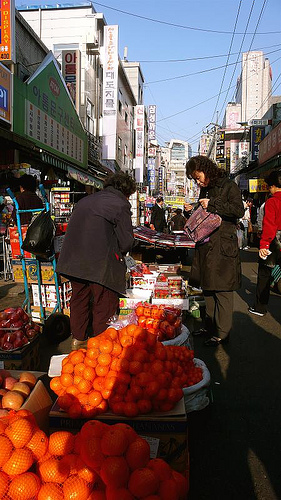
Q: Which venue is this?
A: This is a market.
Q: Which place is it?
A: It is a market.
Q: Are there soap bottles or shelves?
A: No, there are no shelves or soap bottles.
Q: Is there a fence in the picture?
A: No, there are no fences.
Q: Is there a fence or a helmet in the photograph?
A: No, there are no fences or helmets.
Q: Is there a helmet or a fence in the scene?
A: No, there are no fences or helmets.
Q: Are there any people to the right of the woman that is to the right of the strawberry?
A: Yes, there is a person to the right of the woman.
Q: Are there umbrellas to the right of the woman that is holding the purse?
A: No, there is a person to the right of the woman.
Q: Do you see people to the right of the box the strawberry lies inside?
A: Yes, there is a person to the right of the box.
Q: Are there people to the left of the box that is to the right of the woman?
A: No, the person is to the right of the box.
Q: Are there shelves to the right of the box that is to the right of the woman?
A: No, there is a person to the right of the box.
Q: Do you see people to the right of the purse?
A: Yes, there is a person to the right of the purse.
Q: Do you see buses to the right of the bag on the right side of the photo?
A: No, there is a person to the right of the purse.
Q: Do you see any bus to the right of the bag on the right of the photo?
A: No, there is a person to the right of the purse.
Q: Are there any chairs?
A: No, there are no chairs.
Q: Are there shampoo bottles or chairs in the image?
A: No, there are no chairs or shampoo bottles.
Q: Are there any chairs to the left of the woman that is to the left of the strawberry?
A: No, there is a box to the left of the woman.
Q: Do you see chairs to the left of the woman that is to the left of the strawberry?
A: No, there is a box to the left of the woman.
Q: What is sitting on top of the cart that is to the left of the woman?
A: The box is sitting on top of the cart.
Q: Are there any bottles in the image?
A: No, there are no bottles.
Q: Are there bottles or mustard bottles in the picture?
A: No, there are no bottles or mustard bottles.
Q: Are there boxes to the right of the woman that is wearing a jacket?
A: Yes, there is a box to the right of the woman.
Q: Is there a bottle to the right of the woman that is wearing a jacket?
A: No, there is a box to the right of the woman.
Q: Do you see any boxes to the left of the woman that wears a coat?
A: Yes, there is a box to the left of the woman.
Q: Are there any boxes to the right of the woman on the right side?
A: No, the box is to the left of the woman.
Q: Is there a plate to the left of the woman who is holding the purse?
A: No, there is a box to the left of the woman.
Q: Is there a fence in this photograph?
A: No, there are no fences.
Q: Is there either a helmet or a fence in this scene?
A: No, there are no fences or helmets.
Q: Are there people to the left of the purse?
A: Yes, there is a person to the left of the purse.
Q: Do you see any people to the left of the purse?
A: Yes, there is a person to the left of the purse.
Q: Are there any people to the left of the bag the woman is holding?
A: Yes, there is a person to the left of the purse.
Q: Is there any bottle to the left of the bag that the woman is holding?
A: No, there is a person to the left of the purse.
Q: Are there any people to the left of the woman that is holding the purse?
A: Yes, there is a person to the left of the woman.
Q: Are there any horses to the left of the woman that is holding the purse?
A: No, there is a person to the left of the woman.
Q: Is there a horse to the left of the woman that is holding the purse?
A: No, there is a person to the left of the woman.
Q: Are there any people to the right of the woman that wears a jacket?
A: Yes, there is a person to the right of the woman.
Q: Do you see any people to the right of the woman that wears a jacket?
A: Yes, there is a person to the right of the woman.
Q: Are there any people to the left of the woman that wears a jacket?
A: No, the person is to the right of the woman.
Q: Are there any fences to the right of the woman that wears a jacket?
A: No, there is a person to the right of the woman.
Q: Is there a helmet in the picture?
A: No, there are no helmets.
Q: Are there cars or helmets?
A: No, there are no helmets or cars.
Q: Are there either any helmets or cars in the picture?
A: No, there are no helmets or cars.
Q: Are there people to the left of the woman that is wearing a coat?
A: Yes, there is a person to the left of the woman.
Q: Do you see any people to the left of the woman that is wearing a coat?
A: Yes, there is a person to the left of the woman.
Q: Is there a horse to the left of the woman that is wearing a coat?
A: No, there is a person to the left of the woman.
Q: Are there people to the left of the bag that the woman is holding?
A: Yes, there is a person to the left of the purse.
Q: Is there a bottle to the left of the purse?
A: No, there is a person to the left of the purse.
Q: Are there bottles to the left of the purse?
A: No, there is a person to the left of the purse.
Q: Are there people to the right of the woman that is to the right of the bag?
A: Yes, there is a person to the right of the woman.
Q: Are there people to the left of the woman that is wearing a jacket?
A: No, the person is to the right of the woman.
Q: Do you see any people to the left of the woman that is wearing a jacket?
A: No, the person is to the right of the woman.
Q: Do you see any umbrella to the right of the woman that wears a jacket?
A: No, there is a person to the right of the woman.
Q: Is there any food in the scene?
A: Yes, there is food.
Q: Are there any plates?
A: No, there are no plates.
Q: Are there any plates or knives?
A: No, there are no plates or knives.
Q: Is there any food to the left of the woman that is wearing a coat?
A: Yes, there is food to the left of the woman.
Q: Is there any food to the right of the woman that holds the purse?
A: No, the food is to the left of the woman.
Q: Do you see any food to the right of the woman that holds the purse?
A: No, the food is to the left of the woman.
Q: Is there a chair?
A: No, there are no chairs.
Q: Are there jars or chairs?
A: No, there are no chairs or jars.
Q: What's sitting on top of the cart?
A: The box is sitting on top of the cart.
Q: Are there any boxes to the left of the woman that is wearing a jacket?
A: Yes, there is a box to the left of the woman.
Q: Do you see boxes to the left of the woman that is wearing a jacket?
A: Yes, there is a box to the left of the woman.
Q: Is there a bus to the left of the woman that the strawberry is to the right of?
A: No, there is a box to the left of the woman.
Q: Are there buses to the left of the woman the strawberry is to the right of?
A: No, there is a box to the left of the woman.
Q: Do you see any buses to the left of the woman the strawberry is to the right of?
A: No, there is a box to the left of the woman.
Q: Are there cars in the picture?
A: No, there are no cars.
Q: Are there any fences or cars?
A: No, there are no cars or fences.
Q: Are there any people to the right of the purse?
A: Yes, there is a person to the right of the purse.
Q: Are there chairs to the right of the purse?
A: No, there is a person to the right of the purse.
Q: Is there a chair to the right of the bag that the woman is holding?
A: No, there is a person to the right of the purse.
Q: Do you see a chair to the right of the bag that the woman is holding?
A: No, there is a person to the right of the purse.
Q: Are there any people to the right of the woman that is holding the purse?
A: Yes, there is a person to the right of the woman.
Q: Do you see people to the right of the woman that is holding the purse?
A: Yes, there is a person to the right of the woman.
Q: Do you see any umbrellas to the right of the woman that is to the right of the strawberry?
A: No, there is a person to the right of the woman.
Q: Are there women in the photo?
A: Yes, there is a woman.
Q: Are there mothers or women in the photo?
A: Yes, there is a woman.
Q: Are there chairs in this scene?
A: No, there are no chairs.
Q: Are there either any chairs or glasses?
A: No, there are no chairs or glasses.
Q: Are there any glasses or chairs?
A: No, there are no chairs or glasses.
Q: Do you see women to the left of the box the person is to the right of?
A: Yes, there is a woman to the left of the box.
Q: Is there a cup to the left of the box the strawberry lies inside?
A: No, there is a woman to the left of the box.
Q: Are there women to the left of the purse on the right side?
A: Yes, there is a woman to the left of the purse.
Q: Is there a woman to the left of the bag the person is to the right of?
A: Yes, there is a woman to the left of the purse.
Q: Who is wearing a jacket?
A: The woman is wearing a jacket.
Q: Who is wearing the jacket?
A: The woman is wearing a jacket.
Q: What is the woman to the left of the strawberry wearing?
A: The woman is wearing a jacket.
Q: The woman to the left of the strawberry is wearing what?
A: The woman is wearing a jacket.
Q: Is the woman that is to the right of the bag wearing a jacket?
A: Yes, the woman is wearing a jacket.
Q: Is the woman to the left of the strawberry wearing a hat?
A: No, the woman is wearing a jacket.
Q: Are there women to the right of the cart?
A: Yes, there is a woman to the right of the cart.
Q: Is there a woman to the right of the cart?
A: Yes, there is a woman to the right of the cart.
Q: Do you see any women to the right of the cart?
A: Yes, there is a woman to the right of the cart.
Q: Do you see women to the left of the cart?
A: No, the woman is to the right of the cart.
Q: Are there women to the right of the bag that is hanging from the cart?
A: Yes, there is a woman to the right of the bag.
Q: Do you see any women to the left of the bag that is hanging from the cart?
A: No, the woman is to the right of the bag.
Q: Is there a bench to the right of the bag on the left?
A: No, there is a woman to the right of the bag.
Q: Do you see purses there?
A: Yes, there is a purse.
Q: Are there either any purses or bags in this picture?
A: Yes, there is a purse.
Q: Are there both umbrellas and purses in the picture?
A: No, there is a purse but no umbrellas.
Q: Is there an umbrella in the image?
A: No, there are no umbrellas.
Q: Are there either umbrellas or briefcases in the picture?
A: No, there are no umbrellas or briefcases.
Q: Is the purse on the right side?
A: Yes, the purse is on the right of the image.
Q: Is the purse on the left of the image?
A: No, the purse is on the right of the image.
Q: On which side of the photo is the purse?
A: The purse is on the right of the image.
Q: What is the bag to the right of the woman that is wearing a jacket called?
A: The bag is a purse.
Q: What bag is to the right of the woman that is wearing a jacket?
A: The bag is a purse.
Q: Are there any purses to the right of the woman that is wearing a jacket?
A: Yes, there is a purse to the right of the woman.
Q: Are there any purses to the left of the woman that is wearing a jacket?
A: No, the purse is to the right of the woman.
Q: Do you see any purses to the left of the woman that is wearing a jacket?
A: No, the purse is to the right of the woman.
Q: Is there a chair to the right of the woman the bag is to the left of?
A: No, there is a purse to the right of the woman.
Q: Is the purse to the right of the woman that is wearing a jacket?
A: Yes, the purse is to the right of the woman.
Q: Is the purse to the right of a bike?
A: No, the purse is to the right of the woman.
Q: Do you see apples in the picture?
A: Yes, there is an apple.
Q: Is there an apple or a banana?
A: Yes, there is an apple.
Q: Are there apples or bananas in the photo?
A: Yes, there is an apple.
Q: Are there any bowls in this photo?
A: No, there are no bowls.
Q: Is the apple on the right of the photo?
A: No, the apple is on the left of the image.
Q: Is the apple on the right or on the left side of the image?
A: The apple is on the left of the image.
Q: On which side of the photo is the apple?
A: The apple is on the left of the image.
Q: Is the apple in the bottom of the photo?
A: Yes, the apple is in the bottom of the image.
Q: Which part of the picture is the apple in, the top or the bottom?
A: The apple is in the bottom of the image.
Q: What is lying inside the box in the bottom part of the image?
A: The apple is lying inside the box.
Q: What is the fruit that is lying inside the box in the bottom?
A: The fruit is an apple.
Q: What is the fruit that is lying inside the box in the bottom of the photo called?
A: The fruit is an apple.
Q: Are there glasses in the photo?
A: No, there are no glasses.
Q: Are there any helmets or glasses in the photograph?
A: No, there are no glasses or helmets.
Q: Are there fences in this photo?
A: No, there are no fences.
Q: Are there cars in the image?
A: No, there are no cars.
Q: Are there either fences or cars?
A: No, there are no cars or fences.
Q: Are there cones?
A: No, there are no cones.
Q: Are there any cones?
A: No, there are no cones.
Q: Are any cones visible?
A: No, there are no cones.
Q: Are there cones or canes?
A: No, there are no cones or canes.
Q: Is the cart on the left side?
A: Yes, the cart is on the left of the image.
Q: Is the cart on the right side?
A: No, the cart is on the left of the image.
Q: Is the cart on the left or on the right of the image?
A: The cart is on the left of the image.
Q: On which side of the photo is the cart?
A: The cart is on the left of the image.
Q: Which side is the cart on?
A: The cart is on the left of the image.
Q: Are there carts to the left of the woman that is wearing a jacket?
A: Yes, there is a cart to the left of the woman.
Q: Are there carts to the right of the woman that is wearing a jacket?
A: No, the cart is to the left of the woman.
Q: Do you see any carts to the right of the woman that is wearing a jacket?
A: No, the cart is to the left of the woman.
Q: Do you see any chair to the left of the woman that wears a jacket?
A: No, there is a cart to the left of the woman.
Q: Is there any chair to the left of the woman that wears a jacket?
A: No, there is a cart to the left of the woman.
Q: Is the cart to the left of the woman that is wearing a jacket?
A: Yes, the cart is to the left of the woman.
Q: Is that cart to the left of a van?
A: No, the cart is to the left of the woman.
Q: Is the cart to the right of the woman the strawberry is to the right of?
A: No, the cart is to the left of the woman.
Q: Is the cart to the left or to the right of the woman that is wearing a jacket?
A: The cart is to the left of the woman.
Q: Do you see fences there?
A: No, there are no fences.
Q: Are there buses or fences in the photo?
A: No, there are no fences or buses.